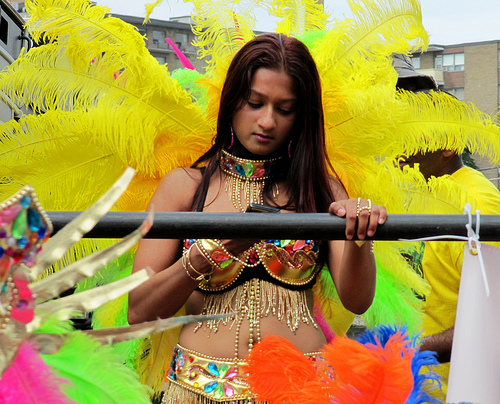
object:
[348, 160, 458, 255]
ground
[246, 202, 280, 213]
phone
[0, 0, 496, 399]
outfit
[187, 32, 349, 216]
hair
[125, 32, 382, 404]
woman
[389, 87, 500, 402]
person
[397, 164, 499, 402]
shirt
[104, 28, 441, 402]
dancer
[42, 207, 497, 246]
pole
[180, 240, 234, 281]
bracelets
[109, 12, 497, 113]
building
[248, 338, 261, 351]
belly button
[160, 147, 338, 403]
costume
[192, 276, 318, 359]
beads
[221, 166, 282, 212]
beads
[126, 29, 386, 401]
dancer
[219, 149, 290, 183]
gems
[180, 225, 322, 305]
stomach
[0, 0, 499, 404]
feather